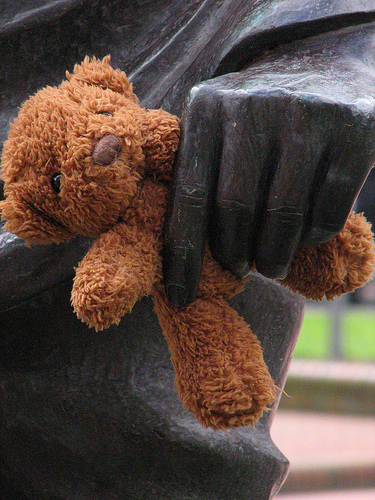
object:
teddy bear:
[1, 57, 374, 430]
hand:
[155, 30, 369, 305]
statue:
[1, 2, 374, 495]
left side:
[2, 1, 375, 494]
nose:
[87, 133, 124, 168]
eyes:
[45, 164, 69, 193]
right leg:
[160, 300, 275, 430]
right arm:
[68, 228, 150, 332]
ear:
[67, 53, 135, 99]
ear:
[0, 191, 73, 251]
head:
[2, 48, 145, 248]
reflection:
[214, 40, 374, 116]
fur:
[5, 61, 373, 424]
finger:
[162, 90, 215, 310]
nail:
[165, 277, 189, 312]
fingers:
[250, 121, 323, 281]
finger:
[212, 128, 259, 280]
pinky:
[304, 131, 371, 258]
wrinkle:
[174, 184, 208, 216]